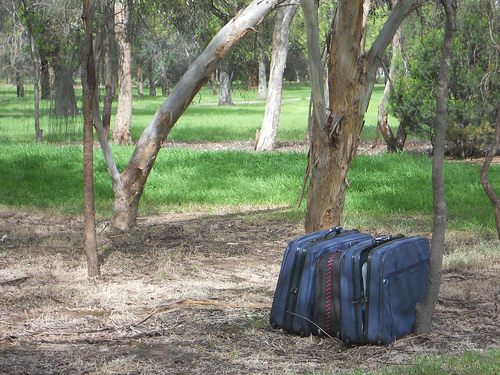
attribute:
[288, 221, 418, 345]
suitcase — blue, sitting, small, close, thick, short, dark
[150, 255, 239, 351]
ground — dirty, brown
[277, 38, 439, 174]
tree — bare, close, brown, lonely, thick, wide, black, light, dead, empty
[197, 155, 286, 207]
grass — blooming, long, short, green, close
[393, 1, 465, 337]
tree — thin, tall, gray